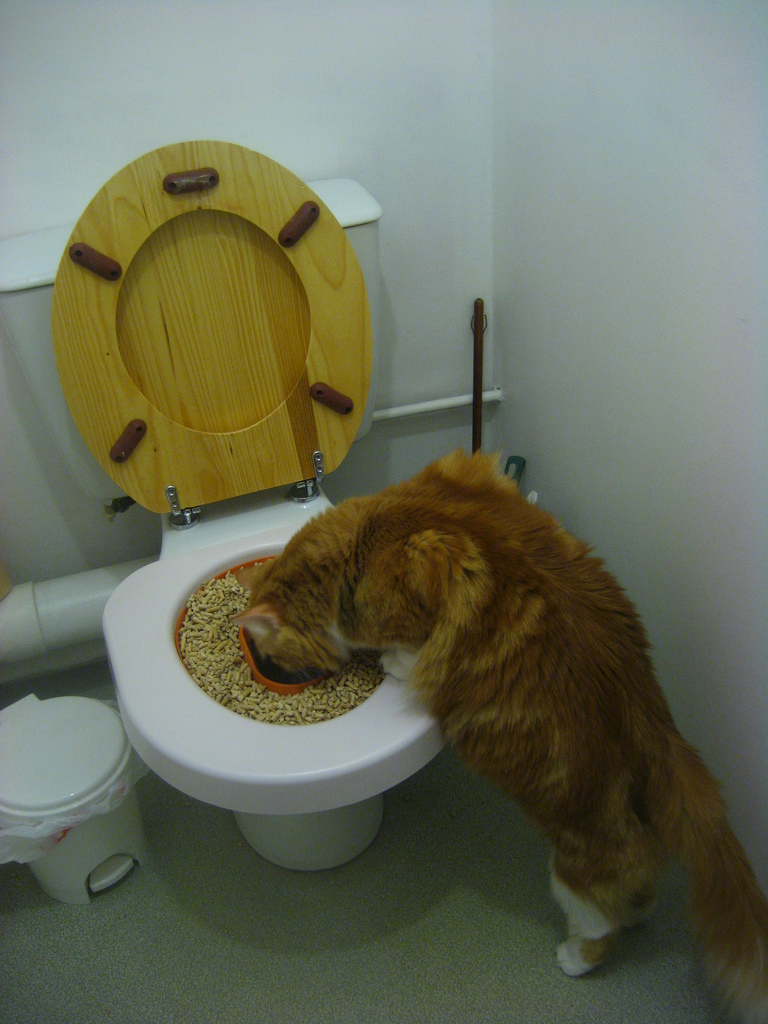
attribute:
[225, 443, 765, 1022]
cat — orange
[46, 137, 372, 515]
toilet seat — wood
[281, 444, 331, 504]
hinge — silver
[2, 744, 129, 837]
trash bag — plastic